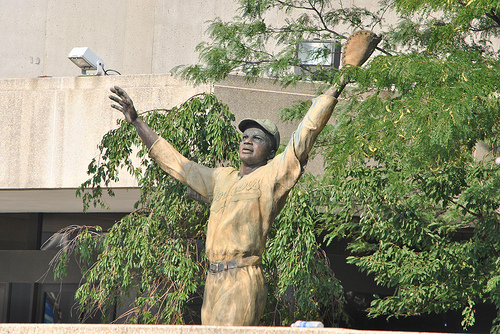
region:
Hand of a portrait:
[276, 27, 404, 224]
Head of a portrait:
[235, 112, 285, 167]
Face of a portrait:
[237, 125, 262, 162]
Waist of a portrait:
[197, 217, 297, 299]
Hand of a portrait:
[96, 70, 226, 202]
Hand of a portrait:
[95, 74, 165, 151]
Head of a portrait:
[215, 95, 277, 166]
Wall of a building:
[21, 57, 116, 193]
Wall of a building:
[23, 95, 138, 250]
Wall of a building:
[100, 20, 269, 95]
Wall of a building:
[19, 3, 241, 56]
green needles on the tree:
[48, 221, 100, 308]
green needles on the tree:
[128, 209, 172, 266]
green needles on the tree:
[339, 229, 420, 310]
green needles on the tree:
[395, 157, 465, 242]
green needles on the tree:
[348, 91, 422, 149]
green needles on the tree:
[183, 34, 273, 100]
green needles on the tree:
[155, 109, 242, 154]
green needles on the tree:
[408, 26, 474, 71]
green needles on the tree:
[228, 16, 335, 83]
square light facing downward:
[67, 47, 102, 74]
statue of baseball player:
[110, 29, 384, 323]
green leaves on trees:
[48, 0, 498, 329]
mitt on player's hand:
[340, 31, 380, 74]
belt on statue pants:
[207, 253, 266, 271]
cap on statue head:
[237, 117, 280, 164]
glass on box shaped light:
[292, 36, 339, 77]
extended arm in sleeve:
[107, 85, 218, 192]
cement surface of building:
[2, 1, 499, 189]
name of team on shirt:
[211, 177, 261, 207]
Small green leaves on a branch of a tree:
[80, 256, 115, 293]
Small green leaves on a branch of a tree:
[95, 221, 130, 251]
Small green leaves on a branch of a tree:
[128, 203, 182, 237]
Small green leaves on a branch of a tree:
[281, 271, 317, 292]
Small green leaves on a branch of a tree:
[288, 214, 333, 246]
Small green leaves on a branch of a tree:
[303, 174, 353, 209]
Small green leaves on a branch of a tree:
[318, 139, 350, 184]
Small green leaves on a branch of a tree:
[331, 109, 378, 145]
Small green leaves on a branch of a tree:
[350, 62, 406, 114]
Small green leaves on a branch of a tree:
[410, 44, 449, 91]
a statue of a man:
[88, 26, 375, 328]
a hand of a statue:
[100, 77, 210, 214]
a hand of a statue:
[286, 17, 388, 194]